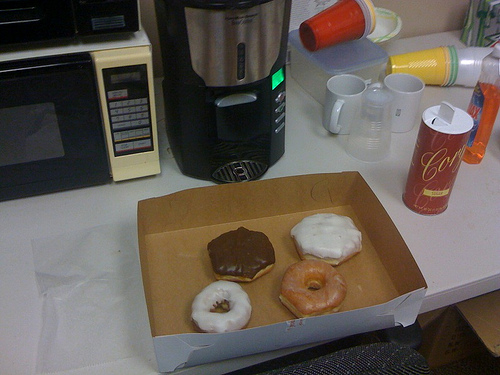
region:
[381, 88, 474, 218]
a canister of cream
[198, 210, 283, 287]
a chocolate frosted donut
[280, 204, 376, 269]
an icing covered donut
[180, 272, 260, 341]
a vanilla frosted donut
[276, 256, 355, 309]
a plain glazed donut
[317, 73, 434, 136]
a pair of white mugs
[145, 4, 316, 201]
a black coffee pot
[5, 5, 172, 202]
an older style microwave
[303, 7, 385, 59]
a red plastic cup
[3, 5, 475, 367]
a small office breakroom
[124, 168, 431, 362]
a box of odd shaped donuts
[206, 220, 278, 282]
a hexagon shaped donut with chocolate icing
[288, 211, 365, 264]
a hexagon shaped donut with vanilla icing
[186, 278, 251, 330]
a round donut with vanilla icing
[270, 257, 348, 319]
a roundish glazed donut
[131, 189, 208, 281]
a cardboard donut box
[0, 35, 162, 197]
a microwave oven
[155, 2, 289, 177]
a coffee maker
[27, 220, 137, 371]
a piece of wax paper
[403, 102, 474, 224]
a container of coffee creamer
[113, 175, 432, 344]
four donuts left in the box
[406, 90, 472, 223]
an open container of sugar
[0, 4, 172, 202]
one microwave on top of the other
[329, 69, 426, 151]
two white mugs on the counter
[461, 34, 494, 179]
a bottle of ajax dish soap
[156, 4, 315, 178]
black and stainless steal coffee and hot chocolate maker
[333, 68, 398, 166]
stack of upside down plastic cups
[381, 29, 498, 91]
plastic cups that have tiped over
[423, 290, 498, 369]
a cardboard box under the table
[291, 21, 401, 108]
a white tuperware bowl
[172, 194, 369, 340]
Four donuts in the box.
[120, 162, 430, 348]
The box is cardboard.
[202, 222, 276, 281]
Chocolate icing on donut.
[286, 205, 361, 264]
Vanilla frosting on donut.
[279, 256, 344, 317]
The donut is glazed.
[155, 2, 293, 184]
Coffe pot is black.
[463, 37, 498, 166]
Dish soap is orange.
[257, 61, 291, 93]
Coffee pot is on.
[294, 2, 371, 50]
the cup is red.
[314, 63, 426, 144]
The cups are empty.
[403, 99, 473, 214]
Coffee creamer that is opened.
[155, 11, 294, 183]
Single use coffee maker.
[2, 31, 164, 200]
Microwave on the counter.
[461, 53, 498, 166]
Dishwashing soap on the counter.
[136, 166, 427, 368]
Cardboard box holding food.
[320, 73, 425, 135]
White coffee cups on the counter.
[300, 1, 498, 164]
Variety of solo cups in a variety of colors.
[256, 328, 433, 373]
Fabric on top of a bench.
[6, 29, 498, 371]
White countertop in the kitchen area.